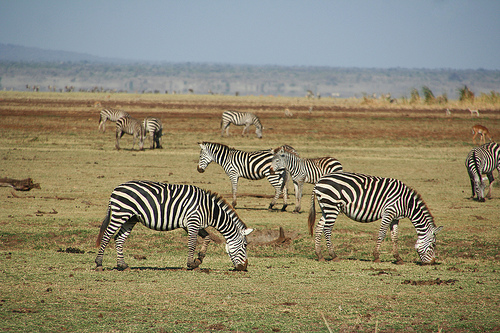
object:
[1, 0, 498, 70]
skies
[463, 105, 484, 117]
animals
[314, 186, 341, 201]
stripe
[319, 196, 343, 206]
stripe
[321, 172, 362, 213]
design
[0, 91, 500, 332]
field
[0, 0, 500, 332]
background